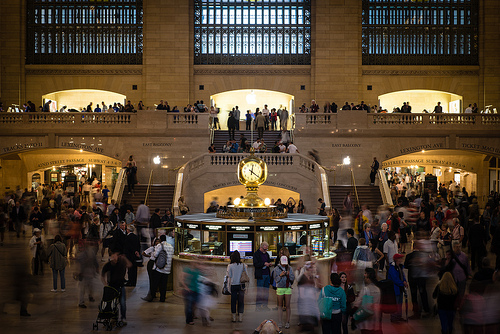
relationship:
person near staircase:
[369, 155, 382, 186] [323, 168, 386, 214]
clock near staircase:
[239, 158, 263, 182] [323, 168, 386, 214]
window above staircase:
[28, 2, 143, 65] [323, 168, 386, 214]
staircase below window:
[323, 168, 386, 214] [28, 2, 143, 65]